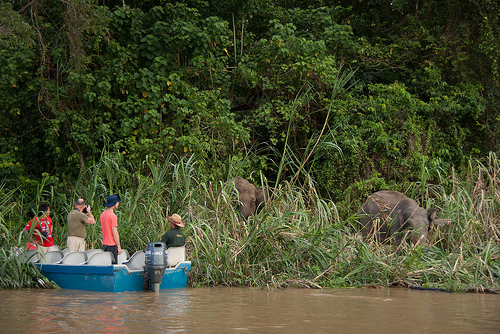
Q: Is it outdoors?
A: Yes, it is outdoors.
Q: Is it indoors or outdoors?
A: It is outdoors.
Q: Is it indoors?
A: No, it is outdoors.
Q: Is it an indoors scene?
A: No, it is outdoors.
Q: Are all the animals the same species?
A: Yes, all the animals are elephants.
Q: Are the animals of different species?
A: No, all the animals are elephants.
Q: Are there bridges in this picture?
A: No, there are no bridges.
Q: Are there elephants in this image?
A: Yes, there is an elephant.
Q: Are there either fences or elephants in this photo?
A: Yes, there is an elephant.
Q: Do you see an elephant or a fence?
A: Yes, there is an elephant.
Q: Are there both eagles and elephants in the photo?
A: No, there is an elephant but no eagles.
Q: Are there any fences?
A: No, there are no fences.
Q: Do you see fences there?
A: No, there are no fences.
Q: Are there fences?
A: No, there are no fences.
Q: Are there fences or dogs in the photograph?
A: No, there are no fences or dogs.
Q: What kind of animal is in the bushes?
A: The animal is an elephant.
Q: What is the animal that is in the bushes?
A: The animal is an elephant.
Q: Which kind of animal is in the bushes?
A: The animal is an elephant.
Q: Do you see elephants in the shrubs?
A: Yes, there is an elephant in the shrubs.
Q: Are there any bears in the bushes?
A: No, there is an elephant in the bushes.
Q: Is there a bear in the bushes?
A: No, there is an elephant in the bushes.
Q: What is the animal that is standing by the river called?
A: The animal is an elephant.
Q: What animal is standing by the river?
A: The animal is an elephant.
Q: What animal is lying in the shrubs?
A: The elephant is lying in the shrubs.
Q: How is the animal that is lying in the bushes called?
A: The animal is an elephant.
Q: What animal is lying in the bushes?
A: The animal is an elephant.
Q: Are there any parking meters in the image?
A: No, there are no parking meters.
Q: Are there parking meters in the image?
A: No, there are no parking meters.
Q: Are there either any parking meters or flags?
A: No, there are no parking meters or flags.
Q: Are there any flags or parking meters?
A: No, there are no parking meters or flags.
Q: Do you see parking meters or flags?
A: No, there are no parking meters or flags.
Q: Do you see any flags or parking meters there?
A: No, there are no parking meters or flags.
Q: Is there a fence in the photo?
A: No, there are no fences.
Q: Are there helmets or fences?
A: No, there are no fences or helmets.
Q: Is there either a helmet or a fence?
A: No, there are no fences or helmets.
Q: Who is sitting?
A: The man is sitting.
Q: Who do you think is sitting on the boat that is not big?
A: The man is sitting on the boat.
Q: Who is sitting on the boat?
A: The man is sitting on the boat.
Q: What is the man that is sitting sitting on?
A: The man is sitting on the boat.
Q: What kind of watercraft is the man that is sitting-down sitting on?
A: The man is sitting on the boat.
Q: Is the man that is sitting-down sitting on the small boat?
A: Yes, the man is sitting on the boat.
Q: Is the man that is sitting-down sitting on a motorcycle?
A: No, the man is sitting on the boat.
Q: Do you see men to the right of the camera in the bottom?
A: Yes, there is a man to the right of the camera.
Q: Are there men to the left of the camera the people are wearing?
A: No, the man is to the right of the camera.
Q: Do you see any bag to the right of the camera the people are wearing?
A: No, there is a man to the right of the camera.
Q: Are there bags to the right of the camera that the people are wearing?
A: No, there is a man to the right of the camera.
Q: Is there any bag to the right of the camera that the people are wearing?
A: No, there is a man to the right of the camera.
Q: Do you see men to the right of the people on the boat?
A: Yes, there is a man to the right of the people.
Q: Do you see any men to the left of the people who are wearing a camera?
A: No, the man is to the right of the people.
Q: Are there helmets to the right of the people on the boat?
A: No, there is a man to the right of the people.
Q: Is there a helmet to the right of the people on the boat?
A: No, there is a man to the right of the people.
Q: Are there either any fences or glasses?
A: No, there are no glasses or fences.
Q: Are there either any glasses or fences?
A: No, there are no glasses or fences.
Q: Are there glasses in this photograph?
A: No, there are no glasses.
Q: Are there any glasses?
A: No, there are no glasses.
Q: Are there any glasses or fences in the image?
A: No, there are no glasses or fences.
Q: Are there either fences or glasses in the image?
A: No, there are no glasses or fences.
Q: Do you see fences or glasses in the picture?
A: No, there are no glasses or fences.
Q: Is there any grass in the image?
A: Yes, there is grass.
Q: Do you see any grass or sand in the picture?
A: Yes, there is grass.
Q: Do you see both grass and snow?
A: No, there is grass but no snow.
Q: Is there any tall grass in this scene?
A: Yes, there is tall grass.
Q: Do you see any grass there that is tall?
A: Yes, there is grass that is tall.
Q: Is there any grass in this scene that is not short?
A: Yes, there is tall grass.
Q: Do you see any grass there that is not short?
A: Yes, there is tall grass.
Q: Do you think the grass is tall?
A: Yes, the grass is tall.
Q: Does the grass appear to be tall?
A: Yes, the grass is tall.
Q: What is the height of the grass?
A: The grass is tall.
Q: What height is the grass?
A: The grass is tall.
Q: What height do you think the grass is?
A: The grass is tall.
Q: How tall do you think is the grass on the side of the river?
A: The grass is tall.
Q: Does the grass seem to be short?
A: No, the grass is tall.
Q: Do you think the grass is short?
A: No, the grass is tall.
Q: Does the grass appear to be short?
A: No, the grass is tall.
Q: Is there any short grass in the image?
A: No, there is grass but it is tall.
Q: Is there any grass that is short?
A: No, there is grass but it is tall.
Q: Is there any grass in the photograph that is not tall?
A: No, there is grass but it is tall.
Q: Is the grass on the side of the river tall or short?
A: The grass is tall.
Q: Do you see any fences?
A: No, there are no fences.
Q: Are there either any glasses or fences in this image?
A: No, there are no fences or glasses.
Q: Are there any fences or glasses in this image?
A: No, there are no fences or glasses.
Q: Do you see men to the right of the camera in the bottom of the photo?
A: Yes, there is a man to the right of the camera.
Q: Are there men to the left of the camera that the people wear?
A: No, the man is to the right of the camera.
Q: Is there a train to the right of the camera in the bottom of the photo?
A: No, there is a man to the right of the camera.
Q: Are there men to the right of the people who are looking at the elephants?
A: Yes, there is a man to the right of the people.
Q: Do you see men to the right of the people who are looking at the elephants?
A: Yes, there is a man to the right of the people.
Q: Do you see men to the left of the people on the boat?
A: No, the man is to the right of the people.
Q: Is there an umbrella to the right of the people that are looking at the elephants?
A: No, there is a man to the right of the people.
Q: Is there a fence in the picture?
A: No, there are no fences.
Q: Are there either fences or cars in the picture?
A: No, there are no fences or cars.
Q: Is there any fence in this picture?
A: No, there are no fences.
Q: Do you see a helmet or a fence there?
A: No, there are no fences or helmets.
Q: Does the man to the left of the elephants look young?
A: Yes, the man is young.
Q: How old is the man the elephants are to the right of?
A: The man is young.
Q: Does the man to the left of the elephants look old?
A: No, the man is young.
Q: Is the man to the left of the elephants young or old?
A: The man is young.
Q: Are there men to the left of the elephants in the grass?
A: Yes, there is a man to the left of the elephants.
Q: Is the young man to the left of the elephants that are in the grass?
A: Yes, the man is to the left of the elephants.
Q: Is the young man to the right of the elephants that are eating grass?
A: No, the man is to the left of the elephants.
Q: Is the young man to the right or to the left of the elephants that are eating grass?
A: The man is to the left of the elephants.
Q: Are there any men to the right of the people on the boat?
A: Yes, there is a man to the right of the people.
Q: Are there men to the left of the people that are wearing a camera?
A: No, the man is to the right of the people.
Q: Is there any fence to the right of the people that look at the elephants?
A: No, there is a man to the right of the people.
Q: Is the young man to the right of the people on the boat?
A: Yes, the man is to the right of the people.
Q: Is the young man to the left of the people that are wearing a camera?
A: No, the man is to the right of the people.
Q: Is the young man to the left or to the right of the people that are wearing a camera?
A: The man is to the right of the people.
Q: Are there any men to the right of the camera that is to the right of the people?
A: Yes, there is a man to the right of the camera.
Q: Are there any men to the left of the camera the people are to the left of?
A: No, the man is to the right of the camera.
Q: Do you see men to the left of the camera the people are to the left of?
A: No, the man is to the right of the camera.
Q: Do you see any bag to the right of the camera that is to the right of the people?
A: No, there is a man to the right of the camera.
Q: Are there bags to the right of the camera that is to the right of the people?
A: No, there is a man to the right of the camera.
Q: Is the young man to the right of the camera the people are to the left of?
A: Yes, the man is to the right of the camera.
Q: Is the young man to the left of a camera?
A: No, the man is to the right of a camera.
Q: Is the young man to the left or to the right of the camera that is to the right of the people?
A: The man is to the right of the camera.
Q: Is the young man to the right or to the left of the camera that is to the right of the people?
A: The man is to the right of the camera.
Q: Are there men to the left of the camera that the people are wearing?
A: No, the man is to the right of the camera.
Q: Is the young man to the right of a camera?
A: Yes, the man is to the right of a camera.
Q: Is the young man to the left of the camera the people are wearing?
A: No, the man is to the right of the camera.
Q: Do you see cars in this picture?
A: No, there are no cars.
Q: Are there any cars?
A: No, there are no cars.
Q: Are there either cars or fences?
A: No, there are no cars or fences.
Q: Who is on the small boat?
A: The people are on the boat.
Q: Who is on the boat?
A: The people are on the boat.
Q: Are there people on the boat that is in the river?
A: Yes, there are people on the boat.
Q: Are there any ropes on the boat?
A: No, there are people on the boat.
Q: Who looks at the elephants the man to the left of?
A: The people look at the elephants.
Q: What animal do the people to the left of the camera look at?
A: The people look at the elephants.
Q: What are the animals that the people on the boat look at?
A: The animals are elephants.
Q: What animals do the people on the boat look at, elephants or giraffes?
A: The people look at elephants.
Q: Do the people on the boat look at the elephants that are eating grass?
A: Yes, the people look at the elephants.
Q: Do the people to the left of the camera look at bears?
A: No, the people look at the elephants.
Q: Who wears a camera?
A: The people wear a camera.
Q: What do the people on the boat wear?
A: The people wear a camera.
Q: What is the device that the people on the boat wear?
A: The device is a camera.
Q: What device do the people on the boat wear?
A: The people wear a camera.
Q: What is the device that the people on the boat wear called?
A: The device is a camera.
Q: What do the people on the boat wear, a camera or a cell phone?
A: The people wear a camera.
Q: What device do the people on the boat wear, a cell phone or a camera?
A: The people wear a camera.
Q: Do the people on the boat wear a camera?
A: Yes, the people wear a camera.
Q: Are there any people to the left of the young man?
A: Yes, there are people to the left of the man.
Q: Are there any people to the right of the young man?
A: No, the people are to the left of the man.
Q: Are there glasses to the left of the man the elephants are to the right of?
A: No, there are people to the left of the man.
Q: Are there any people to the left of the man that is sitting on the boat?
A: Yes, there are people to the left of the man.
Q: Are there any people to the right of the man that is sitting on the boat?
A: No, the people are to the left of the man.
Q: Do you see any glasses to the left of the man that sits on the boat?
A: No, there are people to the left of the man.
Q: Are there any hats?
A: Yes, there is a hat.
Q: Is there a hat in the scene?
A: Yes, there is a hat.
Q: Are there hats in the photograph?
A: Yes, there is a hat.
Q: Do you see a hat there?
A: Yes, there is a hat.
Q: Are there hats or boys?
A: Yes, there is a hat.